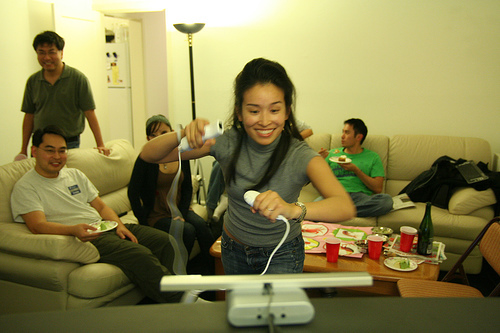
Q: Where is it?
A: This is at the living room.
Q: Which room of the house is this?
A: It is a living room.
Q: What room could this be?
A: It is a living room.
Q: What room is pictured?
A: It is a living room.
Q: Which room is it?
A: It is a living room.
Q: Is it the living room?
A: Yes, it is the living room.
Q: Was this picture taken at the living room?
A: Yes, it was taken in the living room.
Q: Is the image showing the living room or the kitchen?
A: It is showing the living room.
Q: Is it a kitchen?
A: No, it is a living room.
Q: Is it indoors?
A: Yes, it is indoors.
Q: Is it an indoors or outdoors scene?
A: It is indoors.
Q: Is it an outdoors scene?
A: No, it is indoors.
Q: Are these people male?
A: No, they are both male and female.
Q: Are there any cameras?
A: Yes, there is a camera.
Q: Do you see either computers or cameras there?
A: Yes, there is a camera.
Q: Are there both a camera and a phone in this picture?
A: No, there is a camera but no phones.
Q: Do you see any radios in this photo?
A: No, there are no radios.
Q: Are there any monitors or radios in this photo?
A: No, there are no radios or monitors.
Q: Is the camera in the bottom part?
A: Yes, the camera is in the bottom of the image.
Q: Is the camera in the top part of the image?
A: No, the camera is in the bottom of the image.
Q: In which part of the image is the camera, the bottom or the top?
A: The camera is in the bottom of the image.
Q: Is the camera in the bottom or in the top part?
A: The camera is in the bottom of the image.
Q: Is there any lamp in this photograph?
A: Yes, there is a lamp.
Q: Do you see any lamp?
A: Yes, there is a lamp.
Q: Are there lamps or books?
A: Yes, there is a lamp.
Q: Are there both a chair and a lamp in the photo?
A: Yes, there are both a lamp and a chair.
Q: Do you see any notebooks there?
A: No, there are no notebooks.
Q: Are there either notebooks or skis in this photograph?
A: No, there are no notebooks or skis.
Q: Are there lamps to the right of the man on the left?
A: Yes, there is a lamp to the right of the man.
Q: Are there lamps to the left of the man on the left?
A: No, the lamp is to the right of the man.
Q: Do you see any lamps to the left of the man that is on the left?
A: No, the lamp is to the right of the man.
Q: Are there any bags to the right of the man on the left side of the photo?
A: No, there is a lamp to the right of the man.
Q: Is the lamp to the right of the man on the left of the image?
A: Yes, the lamp is to the right of the man.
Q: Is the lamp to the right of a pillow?
A: No, the lamp is to the right of the man.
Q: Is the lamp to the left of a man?
A: No, the lamp is to the right of a man.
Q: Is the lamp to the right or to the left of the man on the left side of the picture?
A: The lamp is to the right of the man.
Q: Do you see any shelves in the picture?
A: No, there are no shelves.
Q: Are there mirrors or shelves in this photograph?
A: No, there are no shelves or mirrors.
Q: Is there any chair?
A: Yes, there is a chair.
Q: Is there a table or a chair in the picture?
A: Yes, there is a chair.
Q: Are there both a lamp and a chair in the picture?
A: Yes, there are both a chair and a lamp.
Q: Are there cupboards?
A: No, there are no cupboards.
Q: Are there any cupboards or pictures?
A: No, there are no cupboards or pictures.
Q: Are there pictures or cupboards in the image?
A: No, there are no cupboards or pictures.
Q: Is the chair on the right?
A: Yes, the chair is on the right of the image.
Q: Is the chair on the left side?
A: No, the chair is on the right of the image.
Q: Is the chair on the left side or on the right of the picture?
A: The chair is on the right of the image.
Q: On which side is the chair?
A: The chair is on the right of the image.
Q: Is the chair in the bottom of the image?
A: Yes, the chair is in the bottom of the image.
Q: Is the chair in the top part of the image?
A: No, the chair is in the bottom of the image.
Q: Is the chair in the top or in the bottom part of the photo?
A: The chair is in the bottom of the image.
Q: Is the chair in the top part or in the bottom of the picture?
A: The chair is in the bottom of the image.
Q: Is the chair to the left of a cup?
A: No, the chair is to the right of a cup.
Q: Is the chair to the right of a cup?
A: Yes, the chair is to the right of a cup.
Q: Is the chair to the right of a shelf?
A: No, the chair is to the right of a cup.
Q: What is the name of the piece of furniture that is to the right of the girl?
A: The piece of furniture is a chair.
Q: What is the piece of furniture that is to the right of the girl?
A: The piece of furniture is a chair.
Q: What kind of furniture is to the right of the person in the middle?
A: The piece of furniture is a chair.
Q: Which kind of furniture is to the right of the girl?
A: The piece of furniture is a chair.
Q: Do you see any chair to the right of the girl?
A: Yes, there is a chair to the right of the girl.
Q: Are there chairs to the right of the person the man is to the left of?
A: Yes, there is a chair to the right of the girl.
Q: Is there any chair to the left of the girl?
A: No, the chair is to the right of the girl.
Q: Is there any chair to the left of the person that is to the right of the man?
A: No, the chair is to the right of the girl.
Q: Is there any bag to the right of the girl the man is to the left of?
A: No, there is a chair to the right of the girl.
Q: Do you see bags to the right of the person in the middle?
A: No, there is a chair to the right of the girl.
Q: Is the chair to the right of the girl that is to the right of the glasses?
A: Yes, the chair is to the right of the girl.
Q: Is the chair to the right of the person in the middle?
A: Yes, the chair is to the right of the girl.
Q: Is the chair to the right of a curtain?
A: No, the chair is to the right of the girl.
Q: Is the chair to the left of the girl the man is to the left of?
A: No, the chair is to the right of the girl.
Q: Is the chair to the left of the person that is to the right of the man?
A: No, the chair is to the right of the girl.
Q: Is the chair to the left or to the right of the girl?
A: The chair is to the right of the girl.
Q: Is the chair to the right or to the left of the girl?
A: The chair is to the right of the girl.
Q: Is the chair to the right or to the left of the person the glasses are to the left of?
A: The chair is to the right of the girl.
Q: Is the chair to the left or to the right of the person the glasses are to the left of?
A: The chair is to the right of the girl.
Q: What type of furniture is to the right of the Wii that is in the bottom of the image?
A: The piece of furniture is a chair.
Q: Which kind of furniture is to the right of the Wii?
A: The piece of furniture is a chair.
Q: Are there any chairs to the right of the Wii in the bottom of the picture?
A: Yes, there is a chair to the right of the Wii.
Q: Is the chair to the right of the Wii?
A: Yes, the chair is to the right of the Wii.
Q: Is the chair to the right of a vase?
A: No, the chair is to the right of the Wii.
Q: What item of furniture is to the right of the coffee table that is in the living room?
A: The piece of furniture is a chair.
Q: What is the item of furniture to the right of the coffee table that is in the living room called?
A: The piece of furniture is a chair.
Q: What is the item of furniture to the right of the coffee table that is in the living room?
A: The piece of furniture is a chair.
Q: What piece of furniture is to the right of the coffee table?
A: The piece of furniture is a chair.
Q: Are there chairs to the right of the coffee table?
A: Yes, there is a chair to the right of the coffee table.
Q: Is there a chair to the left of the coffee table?
A: No, the chair is to the right of the coffee table.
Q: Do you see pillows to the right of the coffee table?
A: No, there is a chair to the right of the coffee table.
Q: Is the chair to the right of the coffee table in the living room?
A: Yes, the chair is to the right of the coffee table.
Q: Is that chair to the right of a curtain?
A: No, the chair is to the right of the coffee table.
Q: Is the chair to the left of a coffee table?
A: No, the chair is to the right of a coffee table.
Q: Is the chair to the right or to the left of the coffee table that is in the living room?
A: The chair is to the right of the coffee table.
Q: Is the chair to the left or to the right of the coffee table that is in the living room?
A: The chair is to the right of the coffee table.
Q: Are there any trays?
A: No, there are no trays.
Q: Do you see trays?
A: No, there are no trays.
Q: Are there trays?
A: No, there are no trays.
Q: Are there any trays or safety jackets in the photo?
A: No, there are no trays or safety jackets.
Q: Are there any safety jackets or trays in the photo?
A: No, there are no trays or safety jackets.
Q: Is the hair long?
A: Yes, the hair is long.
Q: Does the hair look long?
A: Yes, the hair is long.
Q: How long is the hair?
A: The hair is long.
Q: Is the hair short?
A: No, the hair is long.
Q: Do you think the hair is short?
A: No, the hair is long.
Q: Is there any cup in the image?
A: Yes, there is a cup.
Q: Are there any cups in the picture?
A: Yes, there is a cup.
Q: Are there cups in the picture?
A: Yes, there is a cup.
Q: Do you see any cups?
A: Yes, there is a cup.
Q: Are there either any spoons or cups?
A: Yes, there is a cup.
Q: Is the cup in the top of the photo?
A: No, the cup is in the bottom of the image.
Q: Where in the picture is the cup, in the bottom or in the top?
A: The cup is in the bottom of the image.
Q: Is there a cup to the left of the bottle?
A: Yes, there is a cup to the left of the bottle.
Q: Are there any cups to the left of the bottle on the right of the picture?
A: Yes, there is a cup to the left of the bottle.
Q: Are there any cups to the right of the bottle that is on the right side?
A: No, the cup is to the left of the bottle.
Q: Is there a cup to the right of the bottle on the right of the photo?
A: No, the cup is to the left of the bottle.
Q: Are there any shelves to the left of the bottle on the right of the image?
A: No, there is a cup to the left of the bottle.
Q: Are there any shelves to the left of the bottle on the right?
A: No, there is a cup to the left of the bottle.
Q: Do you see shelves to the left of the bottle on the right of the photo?
A: No, there is a cup to the left of the bottle.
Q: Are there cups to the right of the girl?
A: Yes, there is a cup to the right of the girl.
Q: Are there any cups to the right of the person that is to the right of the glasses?
A: Yes, there is a cup to the right of the girl.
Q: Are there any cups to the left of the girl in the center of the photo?
A: No, the cup is to the right of the girl.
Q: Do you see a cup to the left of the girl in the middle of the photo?
A: No, the cup is to the right of the girl.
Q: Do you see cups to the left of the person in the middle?
A: No, the cup is to the right of the girl.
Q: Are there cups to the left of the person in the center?
A: No, the cup is to the right of the girl.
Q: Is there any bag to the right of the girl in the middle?
A: No, there is a cup to the right of the girl.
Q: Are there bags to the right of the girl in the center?
A: No, there is a cup to the right of the girl.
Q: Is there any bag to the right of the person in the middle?
A: No, there is a cup to the right of the girl.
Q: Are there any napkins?
A: No, there are no napkins.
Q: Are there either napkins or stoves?
A: No, there are no napkins or stoves.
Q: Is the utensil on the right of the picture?
A: Yes, the utensil is on the right of the image.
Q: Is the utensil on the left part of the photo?
A: No, the utensil is on the right of the image.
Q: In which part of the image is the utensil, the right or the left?
A: The utensil is on the right of the image.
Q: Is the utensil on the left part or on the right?
A: The utensil is on the right of the image.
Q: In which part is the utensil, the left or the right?
A: The utensil is on the right of the image.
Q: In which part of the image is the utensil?
A: The utensil is on the right of the image.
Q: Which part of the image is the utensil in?
A: The utensil is on the right of the image.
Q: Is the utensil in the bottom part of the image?
A: Yes, the utensil is in the bottom of the image.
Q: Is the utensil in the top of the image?
A: No, the utensil is in the bottom of the image.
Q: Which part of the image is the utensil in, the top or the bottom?
A: The utensil is in the bottom of the image.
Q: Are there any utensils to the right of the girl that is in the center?
A: Yes, there is a utensil to the right of the girl.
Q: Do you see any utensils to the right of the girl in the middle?
A: Yes, there is a utensil to the right of the girl.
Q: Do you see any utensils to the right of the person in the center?
A: Yes, there is a utensil to the right of the girl.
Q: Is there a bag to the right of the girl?
A: No, there is a utensil to the right of the girl.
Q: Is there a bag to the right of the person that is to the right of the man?
A: No, there is a utensil to the right of the girl.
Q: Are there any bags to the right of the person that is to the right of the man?
A: No, there is a utensil to the right of the girl.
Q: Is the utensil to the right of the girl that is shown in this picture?
A: Yes, the utensil is to the right of the girl.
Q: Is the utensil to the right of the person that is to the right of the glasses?
A: Yes, the utensil is to the right of the girl.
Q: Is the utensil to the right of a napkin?
A: No, the utensil is to the right of the girl.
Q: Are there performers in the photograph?
A: No, there are no performers.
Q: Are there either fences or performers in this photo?
A: No, there are no performers or fences.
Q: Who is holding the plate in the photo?
A: The man is holding the plate.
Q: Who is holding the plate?
A: The man is holding the plate.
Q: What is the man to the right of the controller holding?
A: The man is holding the plate.